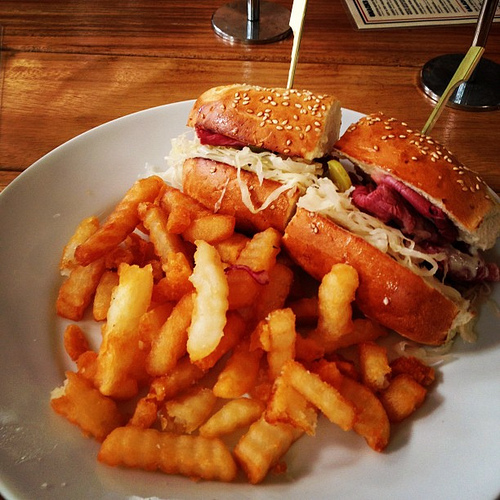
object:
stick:
[411, 1, 500, 114]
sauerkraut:
[167, 127, 315, 192]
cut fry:
[198, 394, 262, 440]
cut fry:
[96, 426, 238, 480]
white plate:
[0, 99, 500, 500]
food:
[50, 84, 499, 478]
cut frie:
[314, 264, 360, 345]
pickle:
[318, 153, 355, 199]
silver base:
[209, 2, 300, 47]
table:
[2, 2, 499, 198]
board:
[0, 0, 497, 188]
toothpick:
[420, 45, 485, 135]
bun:
[333, 110, 499, 250]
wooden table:
[1, 0, 500, 194]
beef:
[351, 174, 498, 282]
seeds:
[195, 84, 342, 148]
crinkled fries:
[48, 178, 433, 485]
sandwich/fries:
[41, 78, 498, 478]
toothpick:
[283, 0, 307, 90]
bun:
[189, 81, 341, 157]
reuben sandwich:
[168, 77, 492, 344]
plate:
[4, 80, 500, 500]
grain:
[11, 6, 483, 136]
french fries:
[55, 174, 435, 477]